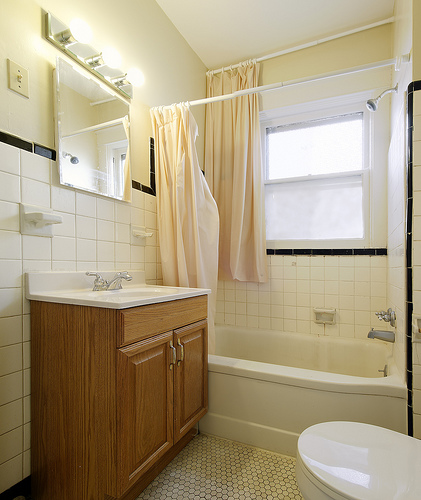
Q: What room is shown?
A: It is a bathroom.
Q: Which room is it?
A: It is a bathroom.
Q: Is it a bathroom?
A: Yes, it is a bathroom.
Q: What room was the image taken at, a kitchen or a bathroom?
A: It was taken at a bathroom.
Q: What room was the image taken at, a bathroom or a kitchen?
A: It was taken at a bathroom.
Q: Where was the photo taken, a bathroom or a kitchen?
A: It was taken at a bathroom.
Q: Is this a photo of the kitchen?
A: No, the picture is showing the bathroom.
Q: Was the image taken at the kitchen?
A: No, the picture was taken in the bathroom.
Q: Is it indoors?
A: Yes, it is indoors.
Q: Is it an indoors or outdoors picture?
A: It is indoors.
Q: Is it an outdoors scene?
A: No, it is indoors.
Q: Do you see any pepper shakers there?
A: No, there are no pepper shakers.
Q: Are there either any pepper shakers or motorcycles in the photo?
A: No, there are no pepper shakers or motorcycles.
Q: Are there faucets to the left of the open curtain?
A: Yes, there is a faucet to the left of the curtain.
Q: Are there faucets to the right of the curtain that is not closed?
A: No, the faucet is to the left of the curtain.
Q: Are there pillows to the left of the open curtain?
A: No, there is a faucet to the left of the curtain.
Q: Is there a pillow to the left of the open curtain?
A: No, there is a faucet to the left of the curtain.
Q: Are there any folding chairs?
A: No, there are no folding chairs.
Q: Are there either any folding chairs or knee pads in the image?
A: No, there are no folding chairs or knee pads.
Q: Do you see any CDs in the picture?
A: No, there are no cds.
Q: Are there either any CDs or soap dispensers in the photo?
A: No, there are no CDs or soap dispensers.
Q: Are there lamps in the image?
A: No, there are no lamps.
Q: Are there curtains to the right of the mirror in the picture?
A: Yes, there is a curtain to the right of the mirror.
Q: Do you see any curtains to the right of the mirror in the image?
A: Yes, there is a curtain to the right of the mirror.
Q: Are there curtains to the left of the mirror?
A: No, the curtain is to the right of the mirror.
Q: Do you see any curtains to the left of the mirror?
A: No, the curtain is to the right of the mirror.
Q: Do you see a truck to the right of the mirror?
A: No, there is a curtain to the right of the mirror.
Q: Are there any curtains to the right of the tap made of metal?
A: Yes, there is a curtain to the right of the faucet.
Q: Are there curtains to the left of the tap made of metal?
A: No, the curtain is to the right of the tap.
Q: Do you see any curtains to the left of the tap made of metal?
A: No, the curtain is to the right of the tap.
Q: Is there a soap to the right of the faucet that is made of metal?
A: No, there is a curtain to the right of the faucet.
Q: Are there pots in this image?
A: No, there are no pots.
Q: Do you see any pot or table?
A: No, there are no pots or tables.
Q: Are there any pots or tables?
A: No, there are no pots or tables.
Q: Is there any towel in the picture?
A: No, there are no towels.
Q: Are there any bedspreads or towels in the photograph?
A: No, there are no towels or bedspreads.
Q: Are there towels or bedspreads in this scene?
A: No, there are no towels or bedspreads.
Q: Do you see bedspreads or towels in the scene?
A: No, there are no towels or bedspreads.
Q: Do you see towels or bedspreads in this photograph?
A: No, there are no towels or bedspreads.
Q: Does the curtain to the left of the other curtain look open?
A: Yes, the curtain is open.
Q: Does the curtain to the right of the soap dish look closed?
A: No, the curtain is open.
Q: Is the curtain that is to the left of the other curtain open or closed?
A: The curtain is open.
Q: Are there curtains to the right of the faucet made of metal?
A: Yes, there is a curtain to the right of the tap.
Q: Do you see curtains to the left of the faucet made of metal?
A: No, the curtain is to the right of the faucet.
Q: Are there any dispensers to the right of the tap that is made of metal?
A: No, there is a curtain to the right of the faucet.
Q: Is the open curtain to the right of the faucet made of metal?
A: Yes, the curtain is to the right of the faucet.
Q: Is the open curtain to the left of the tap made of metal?
A: No, the curtain is to the right of the tap.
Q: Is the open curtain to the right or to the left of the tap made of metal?
A: The curtain is to the right of the tap.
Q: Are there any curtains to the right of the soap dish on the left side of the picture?
A: Yes, there is a curtain to the right of the soap dish.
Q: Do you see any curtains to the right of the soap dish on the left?
A: Yes, there is a curtain to the right of the soap dish.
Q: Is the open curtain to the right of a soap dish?
A: Yes, the curtain is to the right of a soap dish.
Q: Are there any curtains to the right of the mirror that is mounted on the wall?
A: Yes, there is a curtain to the right of the mirror.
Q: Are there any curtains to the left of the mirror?
A: No, the curtain is to the right of the mirror.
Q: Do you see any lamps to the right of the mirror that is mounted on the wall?
A: No, there is a curtain to the right of the mirror.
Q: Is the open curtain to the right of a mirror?
A: Yes, the curtain is to the right of a mirror.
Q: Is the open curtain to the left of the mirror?
A: No, the curtain is to the right of the mirror.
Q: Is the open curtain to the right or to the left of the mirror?
A: The curtain is to the right of the mirror.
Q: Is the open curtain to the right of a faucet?
A: Yes, the curtain is to the right of a faucet.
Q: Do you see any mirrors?
A: Yes, there is a mirror.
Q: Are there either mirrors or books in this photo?
A: Yes, there is a mirror.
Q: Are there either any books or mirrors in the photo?
A: Yes, there is a mirror.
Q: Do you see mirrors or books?
A: Yes, there is a mirror.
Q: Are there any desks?
A: No, there are no desks.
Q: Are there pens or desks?
A: No, there are no desks or pens.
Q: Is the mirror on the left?
A: Yes, the mirror is on the left of the image.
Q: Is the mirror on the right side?
A: No, the mirror is on the left of the image.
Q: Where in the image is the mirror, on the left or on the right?
A: The mirror is on the left of the image.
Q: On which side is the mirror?
A: The mirror is on the left of the image.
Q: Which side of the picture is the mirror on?
A: The mirror is on the left of the image.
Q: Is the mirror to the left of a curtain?
A: Yes, the mirror is to the left of a curtain.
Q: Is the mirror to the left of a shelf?
A: No, the mirror is to the left of a curtain.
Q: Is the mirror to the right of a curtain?
A: No, the mirror is to the left of a curtain.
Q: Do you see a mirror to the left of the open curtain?
A: Yes, there is a mirror to the left of the curtain.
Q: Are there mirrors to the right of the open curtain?
A: No, the mirror is to the left of the curtain.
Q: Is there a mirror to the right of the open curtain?
A: No, the mirror is to the left of the curtain.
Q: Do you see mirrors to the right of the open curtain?
A: No, the mirror is to the left of the curtain.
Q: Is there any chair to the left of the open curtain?
A: No, there is a mirror to the left of the curtain.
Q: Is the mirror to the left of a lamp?
A: No, the mirror is to the left of a curtain.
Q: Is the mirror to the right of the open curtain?
A: No, the mirror is to the left of the curtain.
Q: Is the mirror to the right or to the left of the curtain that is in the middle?
A: The mirror is to the left of the curtain.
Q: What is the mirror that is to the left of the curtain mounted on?
A: The mirror is mounted on the wall.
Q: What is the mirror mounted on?
A: The mirror is mounted on the wall.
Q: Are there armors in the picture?
A: No, there are no armors.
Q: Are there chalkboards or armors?
A: No, there are no armors or chalkboards.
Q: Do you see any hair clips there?
A: No, there are no hair clips.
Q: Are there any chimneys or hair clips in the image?
A: No, there are no hair clips or chimneys.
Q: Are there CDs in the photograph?
A: No, there are no cds.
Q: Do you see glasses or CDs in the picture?
A: No, there are no CDs or glasses.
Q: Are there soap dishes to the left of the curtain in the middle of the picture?
A: Yes, there is a soap dish to the left of the curtain.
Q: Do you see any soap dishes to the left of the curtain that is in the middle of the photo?
A: Yes, there is a soap dish to the left of the curtain.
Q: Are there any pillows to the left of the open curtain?
A: No, there is a soap dish to the left of the curtain.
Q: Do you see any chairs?
A: No, there are no chairs.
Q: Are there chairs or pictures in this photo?
A: No, there are no chairs or pictures.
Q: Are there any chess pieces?
A: No, there are no chess pieces.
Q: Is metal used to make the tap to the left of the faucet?
A: Yes, the tap is made of metal.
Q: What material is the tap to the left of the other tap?
A: The faucet is made of metal.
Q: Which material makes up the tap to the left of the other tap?
A: The faucet is made of metal.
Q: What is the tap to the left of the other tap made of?
A: The faucet is made of metal.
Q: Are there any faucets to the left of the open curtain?
A: Yes, there is a faucet to the left of the curtain.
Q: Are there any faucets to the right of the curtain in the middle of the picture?
A: No, the faucet is to the left of the curtain.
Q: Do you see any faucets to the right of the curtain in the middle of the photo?
A: No, the faucet is to the left of the curtain.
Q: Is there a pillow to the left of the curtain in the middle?
A: No, there is a faucet to the left of the curtain.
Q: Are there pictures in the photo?
A: No, there are no pictures.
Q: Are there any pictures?
A: No, there are no pictures.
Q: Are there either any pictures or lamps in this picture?
A: No, there are no pictures or lamps.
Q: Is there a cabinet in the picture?
A: Yes, there is a cabinet.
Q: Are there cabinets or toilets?
A: Yes, there is a cabinet.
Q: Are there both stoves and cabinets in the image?
A: No, there is a cabinet but no stoves.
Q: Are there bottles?
A: No, there are no bottles.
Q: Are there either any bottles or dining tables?
A: No, there are no bottles or dining tables.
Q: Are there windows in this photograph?
A: Yes, there is a window.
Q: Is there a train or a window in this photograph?
A: Yes, there is a window.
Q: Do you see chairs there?
A: No, there are no chairs.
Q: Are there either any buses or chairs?
A: No, there are no chairs or buses.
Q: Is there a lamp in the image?
A: No, there are no lamps.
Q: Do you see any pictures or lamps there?
A: No, there are no lamps or pictures.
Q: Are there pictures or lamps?
A: No, there are no lamps or pictures.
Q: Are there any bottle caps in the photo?
A: No, there are no bottle caps.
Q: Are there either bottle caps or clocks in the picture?
A: No, there are no bottle caps or clocks.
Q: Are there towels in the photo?
A: No, there are no towels.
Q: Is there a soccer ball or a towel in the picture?
A: No, there are no towels or soccer balls.